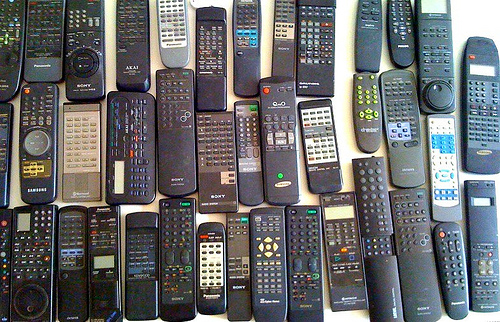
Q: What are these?
A: Remote controls.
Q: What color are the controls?
A: Black.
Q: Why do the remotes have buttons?
A: To make them operate.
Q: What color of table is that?
A: White.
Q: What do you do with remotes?
A: Operate electronic items.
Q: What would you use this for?
A: To control a machine.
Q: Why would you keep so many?
A: Own a lot of equipment.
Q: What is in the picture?
A: Remotes.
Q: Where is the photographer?
A: Looking down at the remotes.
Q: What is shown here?
A: Rows of remotes.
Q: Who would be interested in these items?
A: People who need remotes.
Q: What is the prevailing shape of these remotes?
A: Rectangular.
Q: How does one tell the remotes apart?
A: By size shape, color, and type of buttons.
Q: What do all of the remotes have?
A: Buttons.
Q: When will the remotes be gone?
A: When they are bought, thrown out, or removed.